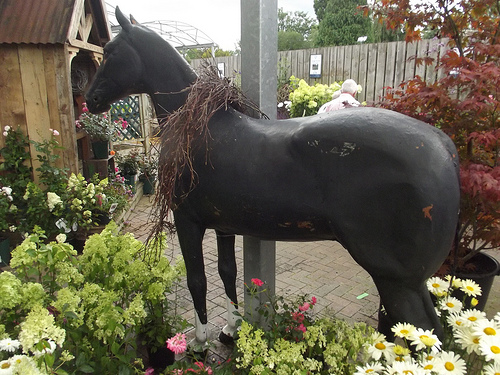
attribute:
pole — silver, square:
[231, 0, 281, 367]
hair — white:
[333, 66, 369, 105]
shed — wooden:
[4, 2, 116, 202]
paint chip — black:
[405, 180, 446, 247]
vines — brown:
[172, 70, 243, 211]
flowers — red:
[158, 325, 220, 370]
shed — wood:
[3, 0, 115, 177]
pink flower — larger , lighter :
[165, 333, 196, 356]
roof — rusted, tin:
[5, 0, 112, 52]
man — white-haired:
[311, 73, 367, 113]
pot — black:
[444, 247, 498, 307]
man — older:
[318, 79, 362, 114]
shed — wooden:
[6, 58, 82, 124]